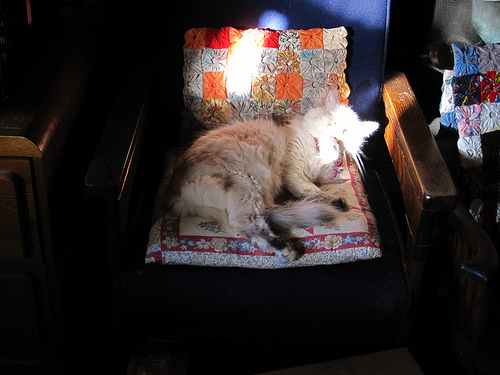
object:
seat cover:
[180, 26, 352, 130]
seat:
[81, 0, 457, 351]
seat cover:
[144, 146, 385, 270]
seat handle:
[380, 68, 460, 216]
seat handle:
[80, 80, 153, 207]